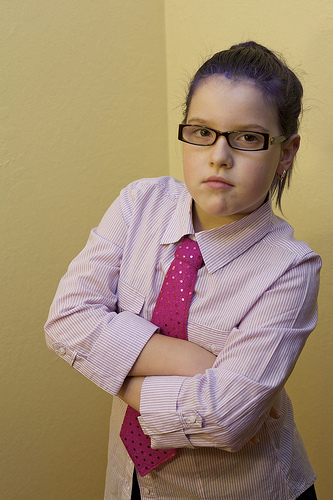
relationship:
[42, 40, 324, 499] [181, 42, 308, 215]
girl has hair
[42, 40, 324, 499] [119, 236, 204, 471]
girl wearing tie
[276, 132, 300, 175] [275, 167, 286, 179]
ear wearing earring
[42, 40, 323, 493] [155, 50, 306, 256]
girl has head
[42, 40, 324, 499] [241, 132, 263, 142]
girl has eye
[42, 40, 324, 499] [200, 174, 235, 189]
girl has mouth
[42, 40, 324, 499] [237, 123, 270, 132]
girl has eyebrow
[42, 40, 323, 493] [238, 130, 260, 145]
girl has eye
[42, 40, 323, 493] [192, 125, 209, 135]
girl has eye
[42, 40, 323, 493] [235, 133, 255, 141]
girl has eye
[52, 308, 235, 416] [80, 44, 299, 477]
arms of girl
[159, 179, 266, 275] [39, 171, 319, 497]
shirt collar of shirt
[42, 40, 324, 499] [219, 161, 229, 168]
girl has nostril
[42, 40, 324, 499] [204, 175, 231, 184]
girl has lip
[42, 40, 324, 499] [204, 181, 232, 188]
girl has lip